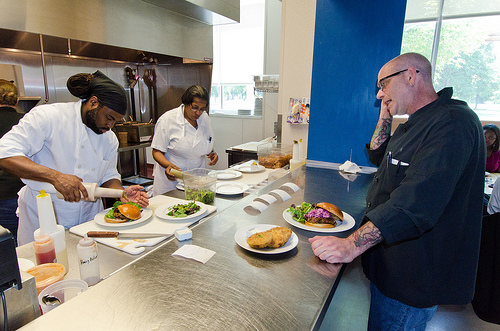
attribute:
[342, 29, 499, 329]
man — bald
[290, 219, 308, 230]
plate — white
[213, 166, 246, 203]
plates — round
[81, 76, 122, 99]
hat — black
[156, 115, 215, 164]
uniform — white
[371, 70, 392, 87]
glasses — black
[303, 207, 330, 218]
onions — purple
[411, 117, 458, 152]
shirt — black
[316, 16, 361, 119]
wall — blue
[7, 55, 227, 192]
two people — working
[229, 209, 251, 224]
countertop — silver, steel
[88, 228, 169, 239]
knife — large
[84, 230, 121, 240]
handle — wooden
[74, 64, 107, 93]
scarf — black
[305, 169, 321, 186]
counter — silver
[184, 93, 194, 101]
hair — black, short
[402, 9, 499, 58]
window — large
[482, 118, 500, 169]
woman — sitting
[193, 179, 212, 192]
bowl — clear, plastic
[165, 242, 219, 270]
paper — white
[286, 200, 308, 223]
salad — green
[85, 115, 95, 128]
beard — dark